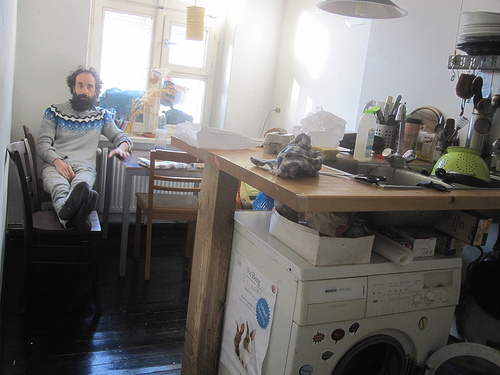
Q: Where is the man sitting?
A: Beside a table.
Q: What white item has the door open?
A: The washing machine.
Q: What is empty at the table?
A: The chair.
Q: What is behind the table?
A: A window.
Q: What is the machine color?
A: White.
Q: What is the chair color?
A: Brown.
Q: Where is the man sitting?
A: Chair.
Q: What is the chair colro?
A: Brown.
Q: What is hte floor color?
A: Black.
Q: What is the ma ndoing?
A: Sitting.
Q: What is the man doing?
A: Sitting.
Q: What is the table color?
A: Brown.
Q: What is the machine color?
A: White.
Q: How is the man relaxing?
A: By resting on 2 chairs.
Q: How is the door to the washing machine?
A: Resting open.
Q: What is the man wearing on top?
A: A sweater.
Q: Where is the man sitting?
A: In the kitchen.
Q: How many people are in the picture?
A: One.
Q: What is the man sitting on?
A: A chair.